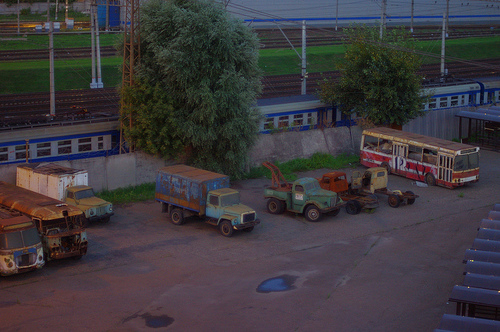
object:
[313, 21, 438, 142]
tree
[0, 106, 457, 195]
fence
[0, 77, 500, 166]
train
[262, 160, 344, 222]
tow truck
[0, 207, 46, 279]
bus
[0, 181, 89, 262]
bus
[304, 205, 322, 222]
wheel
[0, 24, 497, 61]
tracks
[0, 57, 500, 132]
tracks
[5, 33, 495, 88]
grass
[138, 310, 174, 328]
puddle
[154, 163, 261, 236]
blue truck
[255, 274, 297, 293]
puddle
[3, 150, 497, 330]
parking lot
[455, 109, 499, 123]
roof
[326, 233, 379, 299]
cracks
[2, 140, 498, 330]
lot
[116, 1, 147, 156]
tower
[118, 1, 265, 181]
tree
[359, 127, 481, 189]
bus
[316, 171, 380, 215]
truck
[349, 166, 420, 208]
truck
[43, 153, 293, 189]
wall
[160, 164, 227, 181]
rust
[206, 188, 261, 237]
front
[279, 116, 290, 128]
window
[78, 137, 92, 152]
window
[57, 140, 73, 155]
window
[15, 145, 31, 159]
window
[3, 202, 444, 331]
pavement